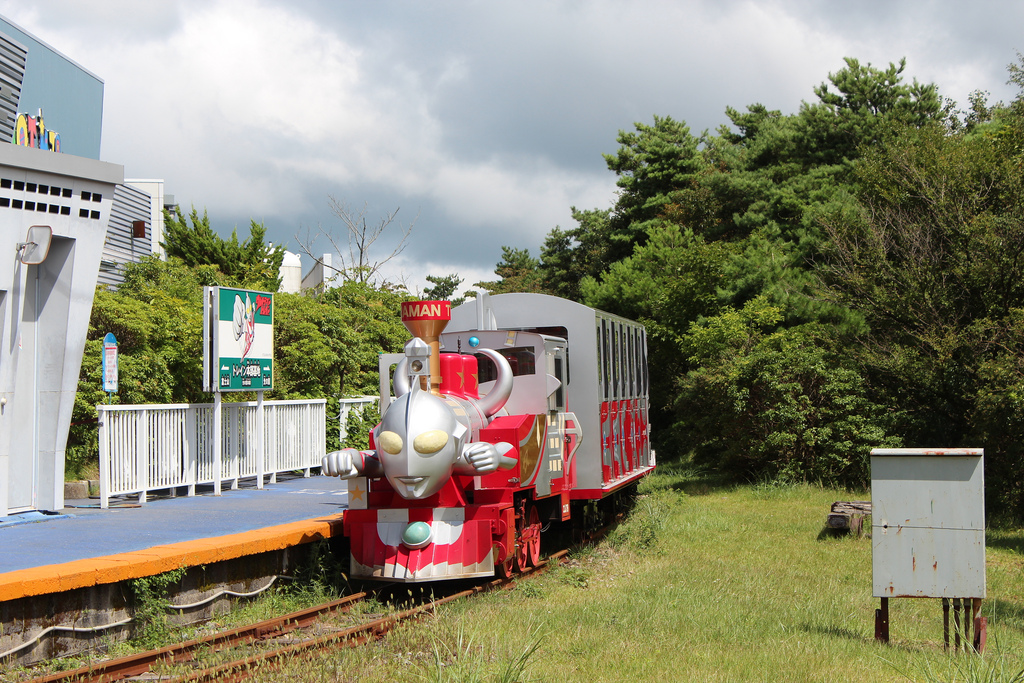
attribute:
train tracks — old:
[42, 553, 565, 677]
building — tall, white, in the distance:
[257, 240, 361, 288]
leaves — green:
[662, 298, 771, 413]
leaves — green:
[683, 350, 755, 430]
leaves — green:
[874, 313, 935, 407]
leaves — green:
[856, 266, 990, 435]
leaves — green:
[832, 97, 930, 206]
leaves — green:
[699, 205, 846, 342]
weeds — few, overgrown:
[240, 605, 444, 670]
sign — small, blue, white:
[96, 325, 122, 403]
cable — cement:
[11, 564, 297, 657]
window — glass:
[9, 176, 29, 190]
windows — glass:
[1, 180, 110, 226]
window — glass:
[1, 180, 110, 219]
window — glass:
[5, 176, 112, 226]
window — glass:
[1, 163, 110, 218]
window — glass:
[1, 171, 105, 247]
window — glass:
[5, 163, 105, 226]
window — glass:
[1, 175, 107, 230]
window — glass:
[10, 176, 106, 229]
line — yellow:
[41, 523, 245, 560]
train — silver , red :
[369, 232, 659, 626]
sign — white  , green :
[192, 264, 301, 420]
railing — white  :
[71, 396, 305, 472]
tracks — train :
[235, 603, 404, 679]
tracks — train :
[129, 595, 469, 660]